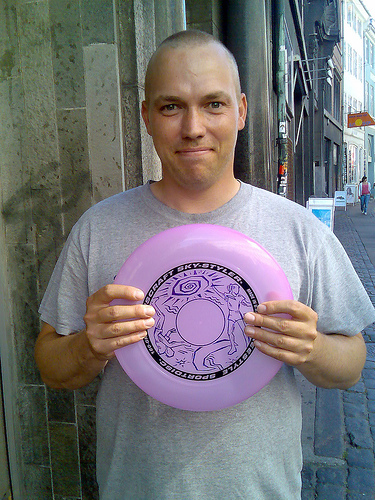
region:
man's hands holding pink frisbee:
[84, 280, 319, 365]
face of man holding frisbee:
[140, 30, 249, 195]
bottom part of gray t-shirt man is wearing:
[96, 413, 300, 499]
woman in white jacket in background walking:
[357, 175, 372, 214]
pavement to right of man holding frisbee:
[319, 415, 373, 475]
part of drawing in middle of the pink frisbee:
[159, 270, 244, 368]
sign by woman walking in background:
[346, 109, 373, 128]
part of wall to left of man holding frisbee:
[51, 53, 137, 183]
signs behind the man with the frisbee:
[307, 188, 348, 223]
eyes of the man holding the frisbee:
[157, 98, 225, 113]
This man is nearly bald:
[128, 20, 279, 199]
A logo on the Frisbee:
[105, 237, 295, 398]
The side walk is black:
[290, 219, 374, 471]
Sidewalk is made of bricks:
[300, 371, 371, 499]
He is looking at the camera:
[154, 96, 237, 120]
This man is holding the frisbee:
[21, 253, 169, 404]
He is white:
[125, 26, 260, 201]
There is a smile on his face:
[157, 137, 235, 181]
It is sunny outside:
[317, 10, 374, 224]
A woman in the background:
[342, 164, 374, 222]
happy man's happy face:
[95, 21, 287, 203]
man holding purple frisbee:
[90, 214, 315, 415]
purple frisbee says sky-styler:
[96, 217, 297, 420]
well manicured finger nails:
[240, 293, 272, 353]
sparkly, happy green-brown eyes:
[152, 96, 237, 117]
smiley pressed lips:
[162, 135, 222, 160]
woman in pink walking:
[352, 172, 370, 219]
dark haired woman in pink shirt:
[355, 170, 370, 210]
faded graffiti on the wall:
[0, 166, 98, 271]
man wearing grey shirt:
[46, 31, 362, 452]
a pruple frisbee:
[96, 220, 306, 418]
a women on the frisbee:
[212, 280, 256, 359]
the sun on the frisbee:
[157, 262, 220, 312]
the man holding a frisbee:
[45, 21, 363, 499]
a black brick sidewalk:
[331, 410, 370, 498]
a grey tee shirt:
[59, 190, 357, 495]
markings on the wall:
[3, 131, 87, 233]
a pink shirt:
[359, 181, 368, 196]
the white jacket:
[357, 180, 374, 197]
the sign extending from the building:
[341, 108, 373, 131]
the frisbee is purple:
[70, 213, 341, 442]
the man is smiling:
[51, 9, 367, 386]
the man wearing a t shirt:
[50, 170, 368, 497]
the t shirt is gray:
[55, 181, 373, 495]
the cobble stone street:
[329, 212, 372, 413]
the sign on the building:
[344, 105, 374, 126]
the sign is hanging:
[339, 96, 373, 131]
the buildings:
[6, 7, 370, 498]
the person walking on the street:
[349, 171, 374, 216]